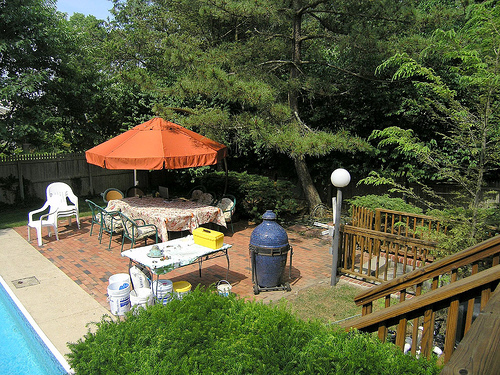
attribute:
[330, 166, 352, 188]
yard light — round, white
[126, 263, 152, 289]
bucket — plastic, white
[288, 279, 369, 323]
grass — a small patch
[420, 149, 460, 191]
ground — wooden, privacy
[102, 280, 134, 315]
bucket — white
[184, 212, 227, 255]
toolbox — yellow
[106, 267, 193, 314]
buckets — gathered, plastic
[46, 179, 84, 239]
stack — white, plastic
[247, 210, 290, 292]
cleaning equipment — blue, large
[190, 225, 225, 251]
box — yellow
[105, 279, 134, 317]
bucket — white, plastic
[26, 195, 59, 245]
chair — white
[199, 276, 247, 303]
bucket — white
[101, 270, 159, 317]
containers — a group 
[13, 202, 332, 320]
patio — brick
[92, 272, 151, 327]
bucket — plastic, white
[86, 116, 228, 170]
umbrella — orange-red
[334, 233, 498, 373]
railing — wooden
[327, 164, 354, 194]
ball light — round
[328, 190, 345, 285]
pole — metal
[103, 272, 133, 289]
bucket — white, plastic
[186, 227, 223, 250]
toolbox — bright yellow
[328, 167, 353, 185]
light — white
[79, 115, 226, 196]
umbrella — red, sunfaded, large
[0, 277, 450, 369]
pool — swimming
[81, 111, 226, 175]
parasol — orange, large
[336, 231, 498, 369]
stairs — wooden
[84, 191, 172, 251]
chairs — green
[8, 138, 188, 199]
fence — high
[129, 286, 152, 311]
bucket — white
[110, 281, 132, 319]
bucket — white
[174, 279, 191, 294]
bucket — yellow